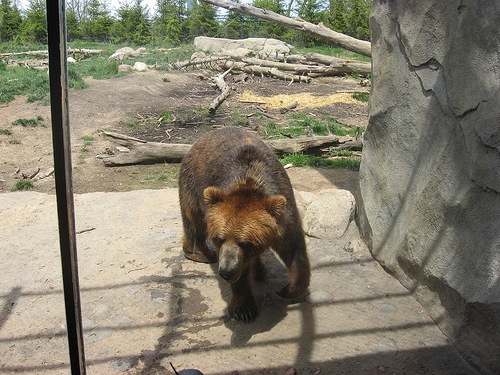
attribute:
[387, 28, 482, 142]
rock wall — light colored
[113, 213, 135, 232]
ground — bare, patched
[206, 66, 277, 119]
logs — on ground, tree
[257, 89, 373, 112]
straw — piled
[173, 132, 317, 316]
bear — small, brown, in a zoo, black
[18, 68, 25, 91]
grass — patched, green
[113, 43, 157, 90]
rocks — large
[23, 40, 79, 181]
window pane — metal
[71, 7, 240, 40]
trees — evergreen, in a row, green, in background, in back